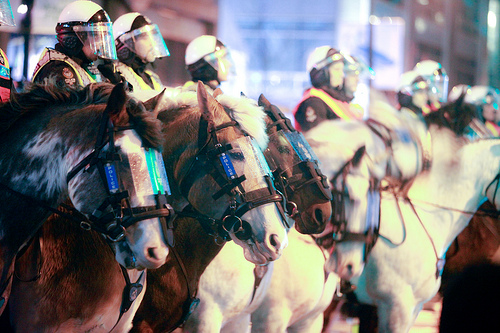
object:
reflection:
[89, 25, 111, 59]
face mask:
[70, 21, 119, 61]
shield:
[108, 147, 171, 196]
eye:
[118, 161, 130, 170]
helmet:
[54, 0, 113, 33]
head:
[54, 0, 113, 61]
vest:
[30, 46, 96, 87]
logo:
[303, 104, 317, 125]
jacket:
[296, 97, 340, 133]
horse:
[376, 135, 500, 330]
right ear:
[106, 81, 128, 117]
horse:
[1, 81, 173, 328]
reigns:
[3, 184, 109, 236]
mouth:
[113, 229, 152, 272]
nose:
[142, 244, 173, 263]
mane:
[2, 80, 166, 152]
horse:
[132, 29, 287, 281]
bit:
[80, 203, 178, 248]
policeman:
[112, 12, 169, 96]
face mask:
[118, 23, 171, 60]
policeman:
[182, 35, 231, 92]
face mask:
[203, 49, 232, 78]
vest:
[113, 62, 163, 93]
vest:
[291, 87, 366, 134]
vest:
[0, 47, 13, 104]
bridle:
[68, 106, 179, 244]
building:
[218, 0, 373, 114]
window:
[263, 38, 299, 70]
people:
[29, 0, 119, 100]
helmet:
[113, 11, 152, 44]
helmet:
[182, 33, 229, 71]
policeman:
[293, 45, 359, 132]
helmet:
[306, 46, 344, 76]